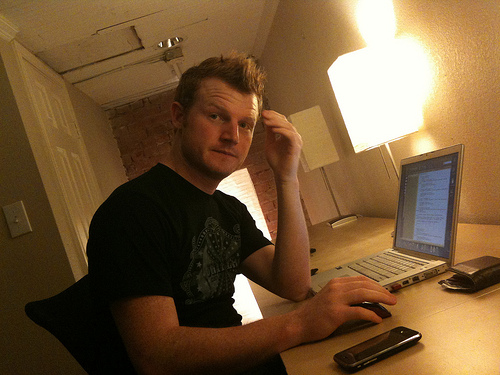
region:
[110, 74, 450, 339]
man in black shirt with laptop computer on desk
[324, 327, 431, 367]
black rectangular phone on desk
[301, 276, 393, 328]
man's right hand is on computer mouse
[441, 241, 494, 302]
man's wallet is on desk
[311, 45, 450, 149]
light with square shade is turned on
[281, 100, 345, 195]
lamp with square shade is not turned on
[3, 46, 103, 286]
white door behind the man on his left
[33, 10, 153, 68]
damaged ceiling tiles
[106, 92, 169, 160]
indoor red brick wall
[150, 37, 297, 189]
man with red hair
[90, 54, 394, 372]
a man in a black shirt sitting at a desk with a wrinkled brow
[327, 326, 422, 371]
a large black smart phone sitting on desktop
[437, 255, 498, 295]
a thick brown leather mans bifold wallet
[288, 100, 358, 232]
table top lamp with a box shade that is not on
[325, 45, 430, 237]
table top lamp on desk with square shade that is turned on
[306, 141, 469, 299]
open laptop computer that is on and connected to the internet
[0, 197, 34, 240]
light switch in down position halfway up wall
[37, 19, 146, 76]
broken area of ceiling with loose tile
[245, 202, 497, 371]
long desk running the length of the wall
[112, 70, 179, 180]
wall made of old looking red bricks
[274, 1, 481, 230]
"There are two lamps"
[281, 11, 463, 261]
"Only one lamp is turned on"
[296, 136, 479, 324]
"The laptop is on"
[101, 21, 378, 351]
"The man is looking at the camera"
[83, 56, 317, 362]
"The man is wearing a black t-shirt"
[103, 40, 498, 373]
"The man is sitting at a desk"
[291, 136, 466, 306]
"The laptop is on the desk"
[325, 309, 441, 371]
"There is a phone on the desk"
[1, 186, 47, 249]
"A light switch is pictured here"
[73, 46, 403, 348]
"His hand is on the computer mouse"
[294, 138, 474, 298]
open laptop on desk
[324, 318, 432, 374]
black and silver cell phone on desk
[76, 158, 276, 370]
black short sleeve shirt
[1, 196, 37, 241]
white wall light switch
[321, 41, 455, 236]
white lamp on desk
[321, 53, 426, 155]
white lamp shade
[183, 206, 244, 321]
green design on front of short sleeve shirt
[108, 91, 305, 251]
brick wall surrounding rooom doorway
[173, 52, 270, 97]
patch of red hair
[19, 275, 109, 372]
back of black chair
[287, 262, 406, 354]
right hand on computer mouse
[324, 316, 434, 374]
cell phone on desk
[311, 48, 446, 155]
lamp with reflection on the wall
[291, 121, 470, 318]
small laptop on the desk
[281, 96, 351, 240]
lamp that is off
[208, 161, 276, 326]
light from the doorway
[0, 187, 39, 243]
light switch on the wall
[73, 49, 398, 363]
man looking at camera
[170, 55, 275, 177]
man with receding hair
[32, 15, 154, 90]
attic access in ceiling